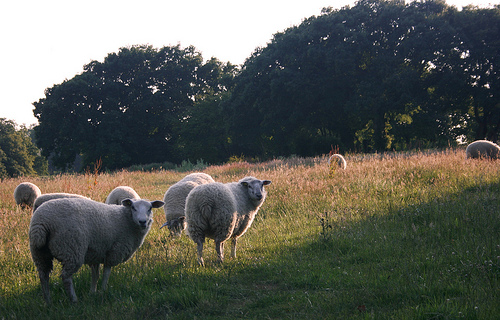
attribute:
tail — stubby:
[28, 221, 46, 249]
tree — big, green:
[176, 2, 495, 161]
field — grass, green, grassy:
[5, 147, 499, 320]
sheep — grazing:
[11, 180, 43, 210]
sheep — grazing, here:
[158, 172, 214, 242]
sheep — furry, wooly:
[183, 176, 273, 269]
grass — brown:
[0, 154, 498, 319]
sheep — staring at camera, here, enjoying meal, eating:
[10, 168, 269, 304]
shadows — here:
[0, 181, 499, 319]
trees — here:
[0, 0, 499, 174]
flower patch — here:
[317, 212, 332, 247]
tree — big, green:
[31, 41, 242, 167]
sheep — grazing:
[33, 191, 84, 219]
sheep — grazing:
[327, 153, 346, 174]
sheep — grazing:
[464, 141, 500, 163]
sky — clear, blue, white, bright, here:
[1, 0, 497, 131]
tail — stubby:
[199, 201, 213, 221]